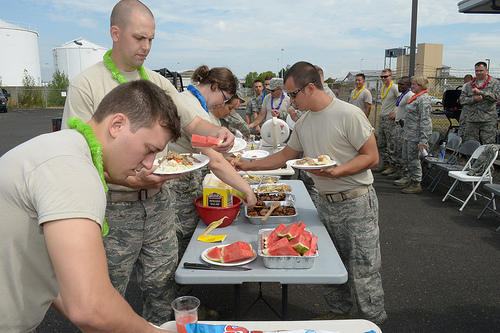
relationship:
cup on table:
[172, 293, 206, 332] [159, 294, 205, 330]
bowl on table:
[188, 193, 242, 222] [174, 150, 370, 330]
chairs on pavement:
[443, 141, 496, 208] [378, 180, 481, 317]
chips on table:
[253, 179, 293, 197] [264, 269, 352, 283]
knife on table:
[181, 259, 253, 276] [178, 160, 389, 330]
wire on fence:
[365, 68, 498, 78] [18, 81, 68, 114]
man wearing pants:
[268, 60, 431, 327] [103, 180, 388, 331]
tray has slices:
[247, 199, 308, 225] [260, 218, 318, 264]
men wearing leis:
[392, 76, 427, 199] [73, 50, 153, 235]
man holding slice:
[268, 60, 431, 327] [190, 130, 230, 154]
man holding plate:
[268, 60, 431, 327] [162, 147, 218, 187]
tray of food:
[247, 199, 308, 225] [210, 137, 334, 274]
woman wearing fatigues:
[161, 66, 222, 227] [111, 189, 392, 328]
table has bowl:
[176, 143, 354, 306] [188, 193, 242, 222]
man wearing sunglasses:
[268, 60, 431, 327] [230, 60, 397, 316]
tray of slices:
[247, 199, 308, 225] [257, 220, 327, 269]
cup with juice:
[172, 293, 206, 332] [165, 283, 202, 329]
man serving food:
[268, 60, 431, 327] [283, 145, 346, 175]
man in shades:
[268, 60, 431, 327] [283, 84, 308, 106]